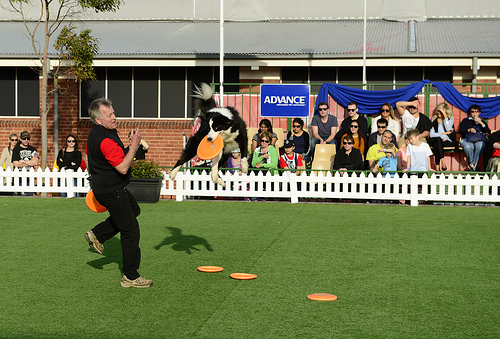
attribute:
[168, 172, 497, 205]
fence — white, pickett, small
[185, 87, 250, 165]
dog — black, white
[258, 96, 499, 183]
people — sitting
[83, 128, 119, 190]
vest — black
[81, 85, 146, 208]
man — balding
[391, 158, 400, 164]
shirt — blue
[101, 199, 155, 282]
pants — black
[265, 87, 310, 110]
sign — blue, white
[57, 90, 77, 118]
wall — brick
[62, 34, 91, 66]
leaves — green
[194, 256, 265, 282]
frisbees — orange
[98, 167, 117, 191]
vest — black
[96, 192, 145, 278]
jeans — black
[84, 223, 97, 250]
shoe — dirty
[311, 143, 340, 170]
chair — empty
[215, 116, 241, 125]
coat — black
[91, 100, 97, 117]
hair — gray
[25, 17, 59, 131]
background — tree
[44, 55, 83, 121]
building — brick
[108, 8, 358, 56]
roof — tin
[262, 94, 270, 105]
word — white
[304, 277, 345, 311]
disc — orange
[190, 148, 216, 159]
disc — flying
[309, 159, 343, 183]
seat — empty